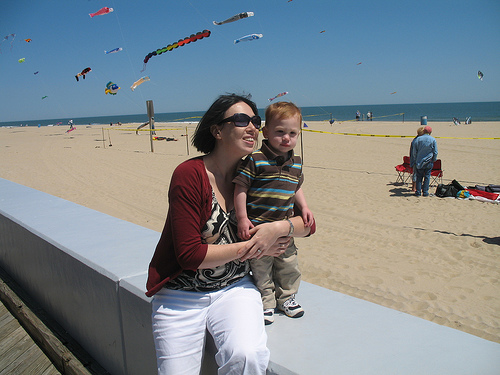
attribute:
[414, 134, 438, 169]
shirt — blue, long sleeve, man's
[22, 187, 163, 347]
wall — wide 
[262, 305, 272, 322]
shoe — boy's, tennis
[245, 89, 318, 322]
child — small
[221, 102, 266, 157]
face — woman's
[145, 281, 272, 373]
pants — white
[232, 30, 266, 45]
kite — multiple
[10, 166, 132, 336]
wall — concrete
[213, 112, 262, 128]
sunglasses — black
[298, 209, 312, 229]
hand — boy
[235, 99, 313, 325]
boy — little 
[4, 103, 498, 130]
water — blue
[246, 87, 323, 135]
hair — brown, boy's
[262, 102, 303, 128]
hair — red 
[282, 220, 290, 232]
wrist — lady's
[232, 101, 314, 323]
child — small, fully dressed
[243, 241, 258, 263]
finger — lady's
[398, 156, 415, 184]
chair — Red 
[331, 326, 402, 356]
concrete — grey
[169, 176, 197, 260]
sweater — brown